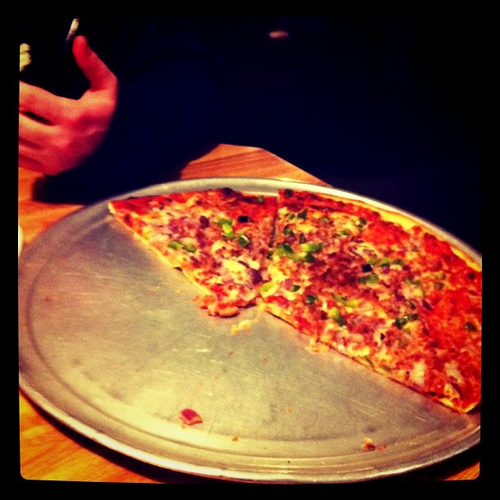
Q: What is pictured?
A: Pizza.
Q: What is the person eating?
A: A Pizza.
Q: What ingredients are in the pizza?
A: Onions, Olives, Cheese, Tomatoe , Flour.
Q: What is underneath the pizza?
A: A metal pan.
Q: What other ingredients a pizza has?
A: Cheese.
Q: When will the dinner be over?
A: When all the pizza is eaten.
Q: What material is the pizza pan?
A: Shinny metal.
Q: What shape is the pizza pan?
A: Circular.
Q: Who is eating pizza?
A: A person.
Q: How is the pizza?
A: Half eaten.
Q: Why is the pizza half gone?
A: It was eaten.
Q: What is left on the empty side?
A: An onion.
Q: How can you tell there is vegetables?
A: Green vegetables.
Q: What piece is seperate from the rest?
A: Far left.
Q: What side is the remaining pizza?
A: Far side.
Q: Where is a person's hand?
A: Top left.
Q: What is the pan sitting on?
A: A table.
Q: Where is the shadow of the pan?
A: At the bottom.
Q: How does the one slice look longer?
A: Cheese on the end.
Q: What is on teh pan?
A: Pizza.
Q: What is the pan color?
A: Silver.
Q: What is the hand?
A: Left.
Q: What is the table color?
A: Brown.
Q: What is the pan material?
A: Metal.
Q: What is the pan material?
A: Metal.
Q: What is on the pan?
A: Pizza.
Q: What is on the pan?
A: Pizza.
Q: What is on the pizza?
A: Pan.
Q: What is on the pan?
A: Pizza.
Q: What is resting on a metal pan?
A: Baked pizza.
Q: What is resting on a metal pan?
A: Baked pizza.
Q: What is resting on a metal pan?
A: Baked pizza.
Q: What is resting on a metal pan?
A: Baked pizza.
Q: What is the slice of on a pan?
A: Pizza.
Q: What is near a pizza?
A: A human hand.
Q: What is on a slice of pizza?
A: Toppings.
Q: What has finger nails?
A: A human hand.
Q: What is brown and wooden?
A: A table.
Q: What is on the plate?
A: Pizza.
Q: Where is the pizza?
A: On the plate.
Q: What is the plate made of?
A: Metal.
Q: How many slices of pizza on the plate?
A: Five.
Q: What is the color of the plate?
A: Silver.